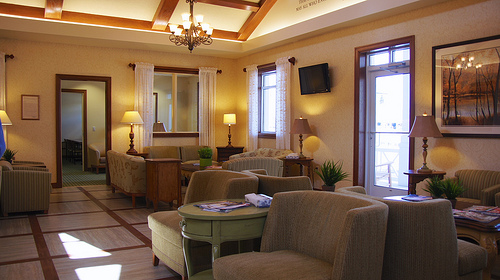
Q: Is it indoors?
A: Yes, it is indoors.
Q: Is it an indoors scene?
A: Yes, it is indoors.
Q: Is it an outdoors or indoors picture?
A: It is indoors.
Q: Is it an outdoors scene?
A: No, it is indoors.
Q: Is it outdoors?
A: No, it is indoors.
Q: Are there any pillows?
A: No, there are no pillows.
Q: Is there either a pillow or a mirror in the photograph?
A: No, there are no pillows or mirrors.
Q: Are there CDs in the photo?
A: No, there are no cds.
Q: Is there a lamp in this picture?
A: Yes, there is a lamp.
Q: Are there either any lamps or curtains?
A: Yes, there is a lamp.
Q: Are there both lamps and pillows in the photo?
A: No, there is a lamp but no pillows.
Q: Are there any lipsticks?
A: No, there are no lipsticks.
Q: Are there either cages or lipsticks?
A: No, there are no lipsticks or cages.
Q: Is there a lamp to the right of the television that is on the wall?
A: Yes, there is a lamp to the right of the TV.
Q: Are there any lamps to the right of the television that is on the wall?
A: Yes, there is a lamp to the right of the TV.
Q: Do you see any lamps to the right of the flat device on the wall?
A: Yes, there is a lamp to the right of the TV.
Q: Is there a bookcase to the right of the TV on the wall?
A: No, there is a lamp to the right of the TV.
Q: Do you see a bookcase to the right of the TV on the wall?
A: No, there is a lamp to the right of the TV.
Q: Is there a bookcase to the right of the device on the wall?
A: No, there is a lamp to the right of the TV.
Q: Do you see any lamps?
A: Yes, there is a lamp.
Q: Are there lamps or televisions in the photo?
A: Yes, there is a lamp.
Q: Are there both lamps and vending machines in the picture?
A: No, there is a lamp but no vending machines.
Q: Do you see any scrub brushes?
A: No, there are no scrub brushes.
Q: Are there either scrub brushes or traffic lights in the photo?
A: No, there are no scrub brushes or traffic lights.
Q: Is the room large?
A: Yes, the room is large.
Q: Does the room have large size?
A: Yes, the room is large.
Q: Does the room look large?
A: Yes, the room is large.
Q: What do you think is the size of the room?
A: The room is large.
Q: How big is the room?
A: The room is large.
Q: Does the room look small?
A: No, the room is large.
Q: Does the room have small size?
A: No, the room is large.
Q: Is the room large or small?
A: The room is large.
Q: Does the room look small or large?
A: The room is large.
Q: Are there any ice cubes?
A: No, there are no ice cubes.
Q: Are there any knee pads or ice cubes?
A: No, there are no ice cubes or knee pads.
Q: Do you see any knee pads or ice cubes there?
A: No, there are no ice cubes or knee pads.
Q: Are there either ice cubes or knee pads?
A: No, there are no ice cubes or knee pads.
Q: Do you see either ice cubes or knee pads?
A: No, there are no ice cubes or knee pads.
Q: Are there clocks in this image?
A: No, there are no clocks.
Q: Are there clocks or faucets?
A: No, there are no clocks or faucets.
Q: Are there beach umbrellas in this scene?
A: No, there are no beach umbrellas.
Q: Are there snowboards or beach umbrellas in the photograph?
A: No, there are no beach umbrellas or snowboards.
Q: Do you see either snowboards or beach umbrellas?
A: No, there are no beach umbrellas or snowboards.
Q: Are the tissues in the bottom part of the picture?
A: Yes, the tissues are in the bottom of the image.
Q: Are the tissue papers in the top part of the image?
A: No, the tissue papers are in the bottom of the image.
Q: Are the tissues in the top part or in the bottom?
A: The tissues are in the bottom of the image.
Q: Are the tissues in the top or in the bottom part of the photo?
A: The tissues are in the bottom of the image.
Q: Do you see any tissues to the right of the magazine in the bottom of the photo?
A: Yes, there are tissues to the right of the magazine.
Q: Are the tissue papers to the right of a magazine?
A: Yes, the tissue papers are to the right of a magazine.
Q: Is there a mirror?
A: No, there are no mirrors.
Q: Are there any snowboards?
A: No, there are no snowboards.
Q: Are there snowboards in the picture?
A: No, there are no snowboards.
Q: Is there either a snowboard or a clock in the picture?
A: No, there are no snowboards or clocks.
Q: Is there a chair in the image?
A: Yes, there is a chair.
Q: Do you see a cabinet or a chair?
A: Yes, there is a chair.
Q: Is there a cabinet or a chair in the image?
A: Yes, there is a chair.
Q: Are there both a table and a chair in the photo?
A: Yes, there are both a chair and a table.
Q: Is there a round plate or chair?
A: Yes, there is a round chair.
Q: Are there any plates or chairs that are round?
A: Yes, the chair is round.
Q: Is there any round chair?
A: Yes, there is a round chair.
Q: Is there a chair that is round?
A: Yes, there is a round chair.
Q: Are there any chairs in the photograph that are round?
A: Yes, there is a chair that is round.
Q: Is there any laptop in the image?
A: No, there are no laptops.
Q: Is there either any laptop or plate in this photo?
A: No, there are no laptops or plates.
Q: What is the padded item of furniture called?
A: The piece of furniture is a chair.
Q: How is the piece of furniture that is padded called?
A: The piece of furniture is a chair.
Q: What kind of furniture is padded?
A: The furniture is a chair.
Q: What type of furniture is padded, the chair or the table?
A: The chair is padded.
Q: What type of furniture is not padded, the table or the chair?
A: The table is not padded.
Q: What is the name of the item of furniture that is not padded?
A: The piece of furniture is a table.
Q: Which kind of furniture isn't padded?
A: The furniture is a table.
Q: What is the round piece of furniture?
A: The piece of furniture is a chair.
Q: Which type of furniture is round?
A: The furniture is a chair.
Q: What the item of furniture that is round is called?
A: The piece of furniture is a chair.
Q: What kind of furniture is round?
A: The furniture is a chair.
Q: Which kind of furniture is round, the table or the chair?
A: The chair is round.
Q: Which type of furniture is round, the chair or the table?
A: The chair is round.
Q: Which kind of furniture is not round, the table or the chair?
A: The table is not round.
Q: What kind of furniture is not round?
A: The furniture is a table.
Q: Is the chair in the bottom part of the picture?
A: Yes, the chair is in the bottom of the image.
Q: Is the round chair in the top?
A: No, the chair is in the bottom of the image.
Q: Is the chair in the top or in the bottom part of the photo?
A: The chair is in the bottom of the image.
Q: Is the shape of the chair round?
A: Yes, the chair is round.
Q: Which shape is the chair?
A: The chair is round.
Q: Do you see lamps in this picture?
A: Yes, there is a lamp.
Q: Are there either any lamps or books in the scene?
A: Yes, there is a lamp.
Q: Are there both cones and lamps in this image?
A: No, there is a lamp but no cones.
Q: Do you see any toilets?
A: No, there are no toilets.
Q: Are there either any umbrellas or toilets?
A: No, there are no toilets or umbrellas.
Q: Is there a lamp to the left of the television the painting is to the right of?
A: Yes, there is a lamp to the left of the television.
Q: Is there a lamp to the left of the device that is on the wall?
A: Yes, there is a lamp to the left of the television.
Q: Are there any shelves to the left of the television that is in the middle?
A: No, there is a lamp to the left of the television.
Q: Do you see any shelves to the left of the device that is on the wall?
A: No, there is a lamp to the left of the television.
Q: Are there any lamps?
A: Yes, there is a lamp.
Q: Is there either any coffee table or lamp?
A: Yes, there is a lamp.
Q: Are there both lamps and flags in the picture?
A: No, there is a lamp but no flags.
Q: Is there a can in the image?
A: No, there are no cans.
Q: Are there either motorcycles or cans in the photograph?
A: No, there are no cans or motorcycles.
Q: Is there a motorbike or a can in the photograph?
A: No, there are no cans or motorcycles.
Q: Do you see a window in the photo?
A: Yes, there is a window.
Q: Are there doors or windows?
A: Yes, there is a window.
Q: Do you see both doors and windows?
A: Yes, there are both a window and a door.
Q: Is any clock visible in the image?
A: No, there are no clocks.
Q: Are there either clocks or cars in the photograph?
A: No, there are no clocks or cars.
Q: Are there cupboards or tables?
A: Yes, there is a table.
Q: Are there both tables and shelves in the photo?
A: No, there is a table but no shelves.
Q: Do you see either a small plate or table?
A: Yes, there is a small table.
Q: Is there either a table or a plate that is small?
A: Yes, the table is small.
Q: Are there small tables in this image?
A: Yes, there is a small table.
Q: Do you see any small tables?
A: Yes, there is a small table.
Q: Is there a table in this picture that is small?
A: Yes, there is a table that is small.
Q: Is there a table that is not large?
A: Yes, there is a small table.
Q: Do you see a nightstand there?
A: No, there are no nightstands.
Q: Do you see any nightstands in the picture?
A: No, there are no nightstands.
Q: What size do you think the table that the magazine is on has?
A: The table has small size.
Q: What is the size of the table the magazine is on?
A: The table is small.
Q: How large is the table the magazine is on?
A: The table is small.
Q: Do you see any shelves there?
A: No, there are no shelves.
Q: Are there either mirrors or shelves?
A: No, there are no shelves or mirrors.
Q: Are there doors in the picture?
A: Yes, there is a door.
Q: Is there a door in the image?
A: Yes, there is a door.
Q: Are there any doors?
A: Yes, there is a door.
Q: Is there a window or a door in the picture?
A: Yes, there is a door.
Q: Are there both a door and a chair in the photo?
A: Yes, there are both a door and a chair.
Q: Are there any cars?
A: No, there are no cars.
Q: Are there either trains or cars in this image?
A: No, there are no cars or trains.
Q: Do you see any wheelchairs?
A: No, there are no wheelchairs.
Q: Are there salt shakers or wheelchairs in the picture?
A: No, there are no wheelchairs or salt shakers.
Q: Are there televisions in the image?
A: Yes, there is a television.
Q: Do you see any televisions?
A: Yes, there is a television.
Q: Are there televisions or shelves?
A: Yes, there is a television.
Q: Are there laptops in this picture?
A: No, there are no laptops.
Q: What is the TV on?
A: The TV is on the wall.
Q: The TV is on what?
A: The TV is on the wall.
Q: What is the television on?
A: The TV is on the wall.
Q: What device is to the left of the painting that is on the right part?
A: The device is a television.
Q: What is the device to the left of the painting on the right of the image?
A: The device is a television.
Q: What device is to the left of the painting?
A: The device is a television.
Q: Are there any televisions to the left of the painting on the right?
A: Yes, there is a television to the left of the painting.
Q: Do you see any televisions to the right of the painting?
A: No, the television is to the left of the painting.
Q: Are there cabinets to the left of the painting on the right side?
A: No, there is a television to the left of the painting.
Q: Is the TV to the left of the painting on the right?
A: Yes, the TV is to the left of the painting.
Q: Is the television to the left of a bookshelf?
A: No, the television is to the left of the painting.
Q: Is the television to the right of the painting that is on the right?
A: No, the television is to the left of the painting.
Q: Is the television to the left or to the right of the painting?
A: The television is to the left of the painting.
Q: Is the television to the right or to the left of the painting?
A: The television is to the left of the painting.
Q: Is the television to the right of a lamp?
A: Yes, the television is to the right of a lamp.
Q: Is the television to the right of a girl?
A: No, the television is to the right of a lamp.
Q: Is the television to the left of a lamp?
A: No, the television is to the right of a lamp.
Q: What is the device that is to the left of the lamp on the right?
A: The device is a television.